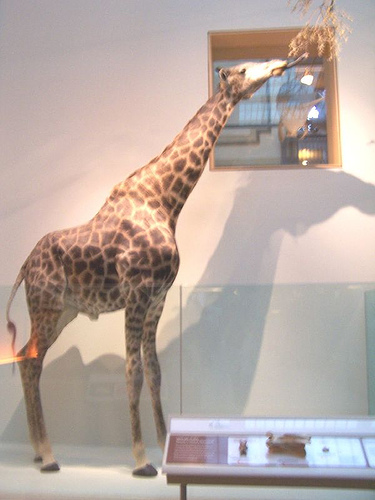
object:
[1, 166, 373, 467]
shadow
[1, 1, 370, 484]
wall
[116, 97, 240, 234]
long neck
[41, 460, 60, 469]
hoof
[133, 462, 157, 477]
hoof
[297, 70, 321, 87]
light reflection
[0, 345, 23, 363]
lens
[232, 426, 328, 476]
podium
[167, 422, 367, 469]
information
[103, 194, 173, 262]
spots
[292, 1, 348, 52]
leaves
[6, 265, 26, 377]
tail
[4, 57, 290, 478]
giraffe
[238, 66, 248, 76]
eye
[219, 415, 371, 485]
blue sky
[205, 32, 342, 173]
window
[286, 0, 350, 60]
branch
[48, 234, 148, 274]
fur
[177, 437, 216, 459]
white lettering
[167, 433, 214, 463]
brown sign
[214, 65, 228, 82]
ears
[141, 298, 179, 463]
leg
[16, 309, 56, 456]
leg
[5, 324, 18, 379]
hair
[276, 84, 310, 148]
reflection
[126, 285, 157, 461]
leg